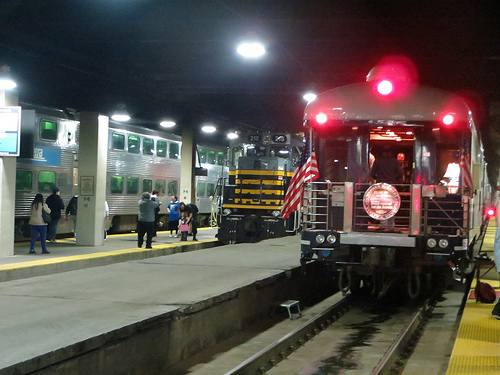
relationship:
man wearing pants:
[126, 189, 165, 254] [133, 216, 157, 248]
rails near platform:
[223, 283, 434, 375] [287, 63, 498, 318]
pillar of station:
[71, 110, 111, 255] [0, 1, 497, 371]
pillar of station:
[1, 88, 24, 272] [0, 1, 497, 371]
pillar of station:
[172, 123, 196, 240] [0, 1, 497, 371]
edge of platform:
[0, 259, 319, 374] [445, 207, 497, 374]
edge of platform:
[473, 197, 498, 271] [445, 207, 497, 374]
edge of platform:
[0, 259, 319, 374] [0, 222, 305, 374]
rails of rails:
[362, 292, 434, 373] [223, 283, 434, 375]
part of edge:
[195, 282, 263, 308] [6, 259, 315, 374]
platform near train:
[2, 218, 334, 317] [229, 79, 478, 272]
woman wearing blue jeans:
[22, 190, 55, 256] [25, 220, 49, 252]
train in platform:
[292, 65, 479, 299] [6, 185, 313, 374]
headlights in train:
[436, 110, 458, 129] [290, 63, 494, 315]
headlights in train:
[372, 71, 399, 102] [290, 63, 494, 315]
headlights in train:
[308, 105, 334, 130] [290, 63, 494, 315]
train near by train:
[226, 130, 291, 228] [290, 63, 494, 315]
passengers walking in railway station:
[23, 182, 203, 255] [7, 63, 298, 366]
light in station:
[235, 40, 265, 58] [0, 1, 497, 371]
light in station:
[2, 78, 17, 91] [0, 1, 497, 371]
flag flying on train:
[280, 152, 316, 222] [280, 74, 499, 296]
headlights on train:
[316, 112, 330, 124] [280, 74, 499, 296]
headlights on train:
[378, 81, 394, 95] [280, 74, 499, 296]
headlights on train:
[442, 115, 456, 126] [280, 74, 499, 296]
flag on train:
[277, 151, 320, 220] [273, 51, 497, 306]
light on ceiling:
[222, 130, 239, 147] [182, 97, 197, 142]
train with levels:
[290, 58, 489, 304] [5, 118, 225, 208]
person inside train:
[387, 149, 412, 185] [280, 74, 499, 296]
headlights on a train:
[378, 81, 394, 95] [280, 74, 499, 296]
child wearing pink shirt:
[171, 219, 193, 250] [175, 218, 197, 228]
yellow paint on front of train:
[446, 215, 500, 375] [215, 128, 306, 242]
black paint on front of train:
[226, 170, 295, 205] [215, 128, 306, 242]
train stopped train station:
[290, 58, 489, 304] [4, 112, 219, 281]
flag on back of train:
[277, 151, 320, 220] [297, 77, 494, 309]